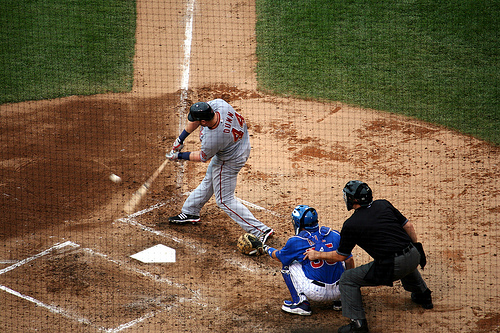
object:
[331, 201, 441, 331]
suit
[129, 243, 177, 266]
plate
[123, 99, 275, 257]
man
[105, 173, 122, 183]
baseball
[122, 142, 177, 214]
bat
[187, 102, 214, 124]
helmet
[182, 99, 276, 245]
uniform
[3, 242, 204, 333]
box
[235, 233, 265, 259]
baseball glove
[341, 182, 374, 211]
face mask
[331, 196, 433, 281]
shirt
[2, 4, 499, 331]
baseball field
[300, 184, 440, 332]
person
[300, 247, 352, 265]
arm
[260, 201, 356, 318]
catcher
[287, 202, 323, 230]
helmet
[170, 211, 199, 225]
shoe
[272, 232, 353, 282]
shirt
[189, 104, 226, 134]
head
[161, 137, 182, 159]
hands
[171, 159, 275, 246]
legs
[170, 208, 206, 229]
foot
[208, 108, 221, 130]
neck